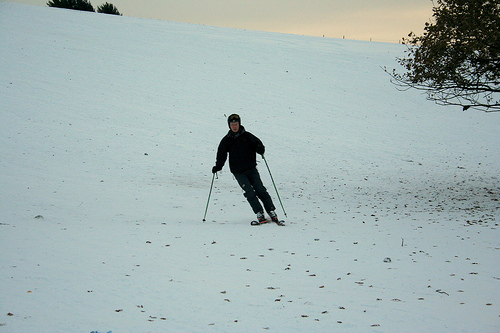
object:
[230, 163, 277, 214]
pants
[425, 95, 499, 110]
branches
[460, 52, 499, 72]
branches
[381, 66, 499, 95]
branches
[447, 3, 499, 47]
branches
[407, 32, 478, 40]
branches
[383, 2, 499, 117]
tree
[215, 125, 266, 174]
coat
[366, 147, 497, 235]
shadow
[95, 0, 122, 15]
trees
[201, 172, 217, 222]
pole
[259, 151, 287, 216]
pole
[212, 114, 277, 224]
man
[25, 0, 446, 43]
sky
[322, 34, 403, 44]
fence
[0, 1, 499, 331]
hill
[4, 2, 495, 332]
snow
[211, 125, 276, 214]
clothes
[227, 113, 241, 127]
helmet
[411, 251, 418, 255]
debris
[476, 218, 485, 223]
debris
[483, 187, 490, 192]
debris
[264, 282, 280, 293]
debris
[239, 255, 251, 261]
debris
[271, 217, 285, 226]
skis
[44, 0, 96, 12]
tree